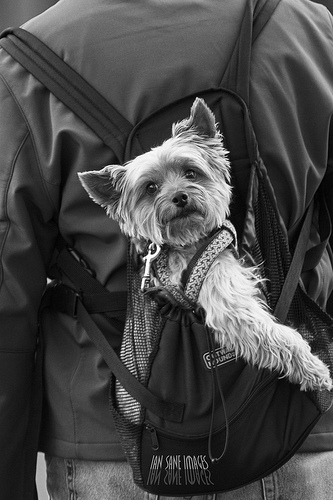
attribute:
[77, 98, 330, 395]
dog — white, furry, surprised, looking, posing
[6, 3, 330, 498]
backpack — black, small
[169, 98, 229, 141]
ear — perked up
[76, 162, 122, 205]
ear — perked up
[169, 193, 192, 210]
nose — black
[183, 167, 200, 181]
eye — black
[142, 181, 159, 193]
eye — black